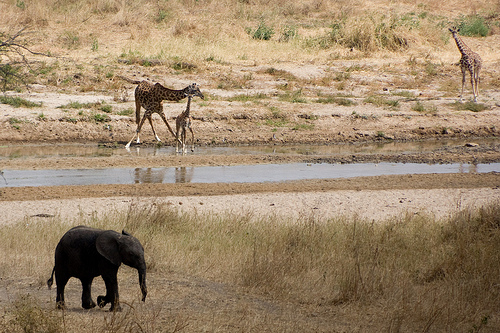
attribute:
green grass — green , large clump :
[88, 106, 120, 126]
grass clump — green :
[34, 112, 49, 120]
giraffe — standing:
[122, 66, 212, 163]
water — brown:
[263, 157, 388, 184]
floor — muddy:
[3, 140, 498, 190]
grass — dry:
[3, 198, 498, 331]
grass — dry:
[0, 0, 499, 57]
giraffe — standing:
[444, 23, 486, 100]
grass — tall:
[201, 203, 498, 328]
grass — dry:
[256, 8, 386, 120]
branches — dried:
[174, 207, 497, 305]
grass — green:
[249, 14, 281, 49]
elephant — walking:
[48, 224, 148, 313]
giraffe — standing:
[120, 57, 220, 154]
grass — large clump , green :
[4, 93, 37, 113]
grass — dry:
[147, 206, 429, 308]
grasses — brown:
[183, 17, 245, 57]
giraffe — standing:
[173, 89, 197, 148]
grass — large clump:
[238, 13, 282, 47]